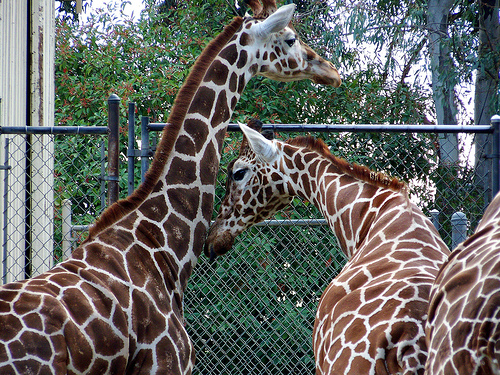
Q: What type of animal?
A: Giraffe.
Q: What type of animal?
A: Giraffe.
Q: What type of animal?
A: Giraffe.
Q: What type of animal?
A: Giraffe.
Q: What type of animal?
A: Giraffe.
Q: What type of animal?
A: Giraffe.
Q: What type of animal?
A: Giraffe.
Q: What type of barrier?
A: Fence.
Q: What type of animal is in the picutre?
A: A giraffe.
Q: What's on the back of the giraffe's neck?
A: Hair.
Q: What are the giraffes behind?
A: A fence.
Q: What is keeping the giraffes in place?
A: A tall fence.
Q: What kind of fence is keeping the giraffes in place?
A: A chain linked fence.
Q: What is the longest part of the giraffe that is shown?
A: The neck.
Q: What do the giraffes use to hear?
A: Their ears.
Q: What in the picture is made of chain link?
A: The fence.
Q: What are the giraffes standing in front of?
A: A fence.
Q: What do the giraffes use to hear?
A: Their ears.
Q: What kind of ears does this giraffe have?
A: White ears.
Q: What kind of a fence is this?
A: A black and green fence.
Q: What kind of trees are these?
A: Green trees.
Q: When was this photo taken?
A: Last week.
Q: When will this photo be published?
A: Next week.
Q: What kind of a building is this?
A: An ivory-colored building.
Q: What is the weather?
A: The weather looks clear and dry.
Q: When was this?
A: Daytime.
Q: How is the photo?
A: Clear.